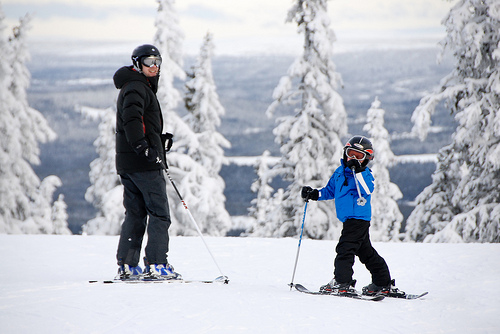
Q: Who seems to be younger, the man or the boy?
A: The boy is younger than the man.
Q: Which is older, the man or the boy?
A: The man is older than the boy.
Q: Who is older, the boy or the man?
A: The man is older than the boy.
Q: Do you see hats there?
A: Yes, there is a hat.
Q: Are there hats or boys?
A: Yes, there is a hat.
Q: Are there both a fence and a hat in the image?
A: No, there is a hat but no fences.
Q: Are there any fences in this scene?
A: No, there are no fences.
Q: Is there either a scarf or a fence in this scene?
A: No, there are no fences or scarves.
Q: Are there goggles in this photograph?
A: Yes, there are goggles.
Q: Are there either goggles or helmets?
A: Yes, there are goggles.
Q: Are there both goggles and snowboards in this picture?
A: No, there are goggles but no snowboards.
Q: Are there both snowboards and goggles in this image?
A: No, there are goggles but no snowboards.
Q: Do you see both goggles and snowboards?
A: No, there are goggles but no snowboards.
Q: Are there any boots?
A: Yes, there are boots.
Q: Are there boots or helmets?
A: Yes, there are boots.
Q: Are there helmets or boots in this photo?
A: Yes, there are boots.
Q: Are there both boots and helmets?
A: Yes, there are both boots and a helmet.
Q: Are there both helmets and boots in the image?
A: Yes, there are both boots and a helmet.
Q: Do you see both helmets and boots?
A: Yes, there are both boots and a helmet.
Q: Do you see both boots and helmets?
A: Yes, there are both boots and a helmet.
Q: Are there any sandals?
A: No, there are no sandals.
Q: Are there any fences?
A: No, there are no fences.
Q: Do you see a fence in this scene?
A: No, there are no fences.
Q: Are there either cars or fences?
A: No, there are no fences or cars.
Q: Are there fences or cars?
A: No, there are no fences or cars.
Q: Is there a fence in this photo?
A: No, there are no fences.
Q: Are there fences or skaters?
A: No, there are no fences or skaters.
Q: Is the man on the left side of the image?
A: Yes, the man is on the left of the image.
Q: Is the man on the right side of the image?
A: No, the man is on the left of the image.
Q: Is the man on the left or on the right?
A: The man is on the left of the image.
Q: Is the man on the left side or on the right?
A: The man is on the left of the image.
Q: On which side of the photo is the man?
A: The man is on the left of the image.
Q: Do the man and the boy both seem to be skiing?
A: Yes, both the man and the boy are skiing.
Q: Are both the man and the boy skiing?
A: Yes, both the man and the boy are skiing.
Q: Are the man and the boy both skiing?
A: Yes, both the man and the boy are skiing.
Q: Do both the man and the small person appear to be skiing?
A: Yes, both the man and the boy are skiing.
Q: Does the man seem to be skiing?
A: Yes, the man is skiing.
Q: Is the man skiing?
A: Yes, the man is skiing.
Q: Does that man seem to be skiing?
A: Yes, the man is skiing.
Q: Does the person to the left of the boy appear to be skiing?
A: Yes, the man is skiing.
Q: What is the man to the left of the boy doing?
A: The man is skiing.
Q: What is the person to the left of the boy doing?
A: The man is skiing.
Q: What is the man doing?
A: The man is skiing.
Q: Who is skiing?
A: The man is skiing.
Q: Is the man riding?
A: No, the man is skiing.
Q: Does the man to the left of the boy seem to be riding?
A: No, the man is skiing.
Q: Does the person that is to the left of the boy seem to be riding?
A: No, the man is skiing.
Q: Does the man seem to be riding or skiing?
A: The man is skiing.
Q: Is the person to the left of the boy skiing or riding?
A: The man is skiing.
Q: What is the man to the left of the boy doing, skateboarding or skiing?
A: The man is skiing.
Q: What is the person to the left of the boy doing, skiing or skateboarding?
A: The man is skiing.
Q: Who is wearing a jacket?
A: The man is wearing a jacket.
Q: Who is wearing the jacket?
A: The man is wearing a jacket.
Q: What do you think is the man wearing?
A: The man is wearing a jacket.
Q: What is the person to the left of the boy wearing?
A: The man is wearing a jacket.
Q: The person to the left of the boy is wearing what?
A: The man is wearing a jacket.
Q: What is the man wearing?
A: The man is wearing a jacket.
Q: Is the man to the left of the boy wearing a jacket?
A: Yes, the man is wearing a jacket.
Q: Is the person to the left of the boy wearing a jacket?
A: Yes, the man is wearing a jacket.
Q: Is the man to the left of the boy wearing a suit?
A: No, the man is wearing a jacket.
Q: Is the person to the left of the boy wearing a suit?
A: No, the man is wearing a jacket.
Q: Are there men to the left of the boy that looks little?
A: Yes, there is a man to the left of the boy.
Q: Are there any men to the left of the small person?
A: Yes, there is a man to the left of the boy.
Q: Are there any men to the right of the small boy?
A: No, the man is to the left of the boy.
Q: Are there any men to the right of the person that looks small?
A: No, the man is to the left of the boy.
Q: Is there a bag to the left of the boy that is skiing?
A: No, there is a man to the left of the boy.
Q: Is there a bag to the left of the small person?
A: No, there is a man to the left of the boy.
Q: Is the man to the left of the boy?
A: Yes, the man is to the left of the boy.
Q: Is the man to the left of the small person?
A: Yes, the man is to the left of the boy.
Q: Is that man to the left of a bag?
A: No, the man is to the left of the boy.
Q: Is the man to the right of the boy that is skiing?
A: No, the man is to the left of the boy.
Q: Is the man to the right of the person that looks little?
A: No, the man is to the left of the boy.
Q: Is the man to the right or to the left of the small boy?
A: The man is to the left of the boy.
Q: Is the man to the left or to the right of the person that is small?
A: The man is to the left of the boy.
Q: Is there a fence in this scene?
A: No, there are no fences.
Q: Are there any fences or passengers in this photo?
A: No, there are no fences or passengers.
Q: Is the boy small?
A: Yes, the boy is small.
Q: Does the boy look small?
A: Yes, the boy is small.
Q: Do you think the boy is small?
A: Yes, the boy is small.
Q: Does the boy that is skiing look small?
A: Yes, the boy is small.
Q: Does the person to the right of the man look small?
A: Yes, the boy is small.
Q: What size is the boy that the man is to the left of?
A: The boy is small.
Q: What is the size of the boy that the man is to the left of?
A: The boy is small.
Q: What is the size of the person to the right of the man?
A: The boy is small.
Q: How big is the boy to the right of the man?
A: The boy is small.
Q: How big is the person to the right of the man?
A: The boy is small.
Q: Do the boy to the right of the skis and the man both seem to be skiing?
A: Yes, both the boy and the man are skiing.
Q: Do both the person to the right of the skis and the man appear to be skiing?
A: Yes, both the boy and the man are skiing.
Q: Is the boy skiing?
A: Yes, the boy is skiing.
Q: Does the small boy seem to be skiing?
A: Yes, the boy is skiing.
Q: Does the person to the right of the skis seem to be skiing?
A: Yes, the boy is skiing.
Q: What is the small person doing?
A: The boy is skiing.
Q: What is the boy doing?
A: The boy is skiing.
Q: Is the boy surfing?
A: No, the boy is skiing.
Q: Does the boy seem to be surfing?
A: No, the boy is skiing.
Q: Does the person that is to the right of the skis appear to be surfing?
A: No, the boy is skiing.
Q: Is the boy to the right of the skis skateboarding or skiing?
A: The boy is skiing.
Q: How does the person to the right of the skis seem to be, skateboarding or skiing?
A: The boy is skiing.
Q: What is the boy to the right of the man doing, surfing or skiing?
A: The boy is skiing.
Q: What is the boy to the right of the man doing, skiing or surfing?
A: The boy is skiing.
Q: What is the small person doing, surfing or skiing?
A: The boy is skiing.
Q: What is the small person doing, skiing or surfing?
A: The boy is skiing.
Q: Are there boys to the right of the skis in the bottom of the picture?
A: Yes, there is a boy to the right of the skis.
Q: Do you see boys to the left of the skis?
A: No, the boy is to the right of the skis.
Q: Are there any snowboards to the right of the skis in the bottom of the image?
A: No, there is a boy to the right of the skis.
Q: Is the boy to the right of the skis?
A: Yes, the boy is to the right of the skis.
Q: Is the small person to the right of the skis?
A: Yes, the boy is to the right of the skis.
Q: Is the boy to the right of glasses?
A: No, the boy is to the right of the skis.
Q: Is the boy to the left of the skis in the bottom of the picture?
A: No, the boy is to the right of the skis.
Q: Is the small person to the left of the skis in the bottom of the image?
A: No, the boy is to the right of the skis.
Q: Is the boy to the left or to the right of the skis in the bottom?
A: The boy is to the right of the skis.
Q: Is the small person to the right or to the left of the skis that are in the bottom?
A: The boy is to the right of the skis.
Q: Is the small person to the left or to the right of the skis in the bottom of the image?
A: The boy is to the right of the skis.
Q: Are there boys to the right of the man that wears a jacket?
A: Yes, there is a boy to the right of the man.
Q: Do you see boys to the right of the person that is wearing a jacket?
A: Yes, there is a boy to the right of the man.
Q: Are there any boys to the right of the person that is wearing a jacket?
A: Yes, there is a boy to the right of the man.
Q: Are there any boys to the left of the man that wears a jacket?
A: No, the boy is to the right of the man.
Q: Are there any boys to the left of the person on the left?
A: No, the boy is to the right of the man.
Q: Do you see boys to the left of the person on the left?
A: No, the boy is to the right of the man.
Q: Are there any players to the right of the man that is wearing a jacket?
A: No, there is a boy to the right of the man.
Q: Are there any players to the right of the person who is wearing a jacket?
A: No, there is a boy to the right of the man.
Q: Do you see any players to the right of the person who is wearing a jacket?
A: No, there is a boy to the right of the man.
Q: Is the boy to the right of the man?
A: Yes, the boy is to the right of the man.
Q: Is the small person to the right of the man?
A: Yes, the boy is to the right of the man.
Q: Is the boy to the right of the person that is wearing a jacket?
A: Yes, the boy is to the right of the man.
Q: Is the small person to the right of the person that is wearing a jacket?
A: Yes, the boy is to the right of the man.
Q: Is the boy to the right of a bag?
A: No, the boy is to the right of the man.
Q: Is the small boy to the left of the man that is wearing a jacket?
A: No, the boy is to the right of the man.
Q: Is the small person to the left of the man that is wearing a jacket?
A: No, the boy is to the right of the man.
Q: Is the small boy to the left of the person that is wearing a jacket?
A: No, the boy is to the right of the man.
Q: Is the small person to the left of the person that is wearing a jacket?
A: No, the boy is to the right of the man.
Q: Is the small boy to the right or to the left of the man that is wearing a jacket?
A: The boy is to the right of the man.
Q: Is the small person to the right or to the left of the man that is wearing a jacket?
A: The boy is to the right of the man.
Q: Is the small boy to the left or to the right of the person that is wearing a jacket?
A: The boy is to the right of the man.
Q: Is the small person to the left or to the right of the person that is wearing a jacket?
A: The boy is to the right of the man.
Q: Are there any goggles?
A: Yes, there are goggles.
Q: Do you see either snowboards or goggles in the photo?
A: Yes, there are goggles.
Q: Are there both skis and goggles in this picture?
A: Yes, there are both goggles and a ski.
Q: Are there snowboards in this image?
A: No, there are no snowboards.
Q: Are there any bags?
A: No, there are no bags.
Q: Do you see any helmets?
A: Yes, there is a helmet.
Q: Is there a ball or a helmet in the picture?
A: Yes, there is a helmet.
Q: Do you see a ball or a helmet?
A: Yes, there is a helmet.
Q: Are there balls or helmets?
A: Yes, there is a helmet.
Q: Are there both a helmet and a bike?
A: No, there is a helmet but no bikes.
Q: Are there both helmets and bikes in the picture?
A: No, there is a helmet but no bikes.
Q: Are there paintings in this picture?
A: No, there are no paintings.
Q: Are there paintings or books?
A: No, there are no paintings or books.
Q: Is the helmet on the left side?
A: No, the helmet is on the right of the image.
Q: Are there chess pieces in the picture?
A: No, there are no chess pieces.